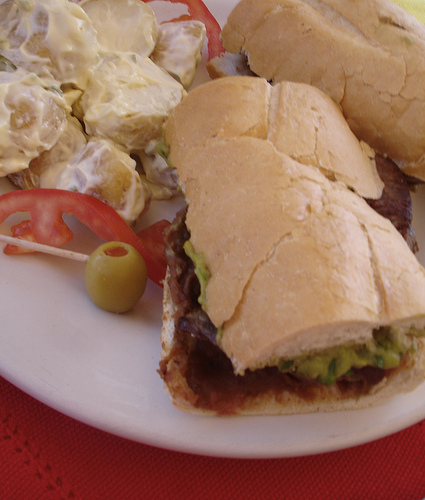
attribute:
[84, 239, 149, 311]
olive — small, green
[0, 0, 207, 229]
potatoes — covered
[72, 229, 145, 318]
olive — green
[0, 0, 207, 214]
potatos — covered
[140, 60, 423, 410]
sandwich — meal, cut in half